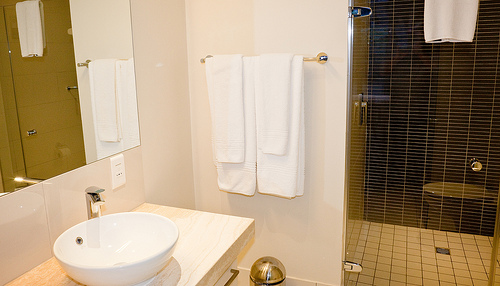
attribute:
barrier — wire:
[351, 11, 496, 283]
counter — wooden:
[0, 202, 258, 284]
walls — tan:
[141, 0, 341, 284]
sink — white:
[48, 211, 182, 283]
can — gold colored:
[251, 254, 286, 283]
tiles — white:
[367, 230, 430, 282]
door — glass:
[340, 2, 499, 284]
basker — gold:
[251, 245, 287, 284]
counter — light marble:
[141, 201, 255, 283]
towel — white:
[202, 50, 247, 169]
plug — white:
[109, 148, 127, 193]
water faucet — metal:
[76, 161, 139, 236]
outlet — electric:
[103, 153, 135, 191]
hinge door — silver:
[345, 248, 362, 280]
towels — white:
[206, 53, 303, 196]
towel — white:
[8, 0, 49, 65]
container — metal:
[248, 247, 288, 277]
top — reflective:
[249, 255, 283, 277]